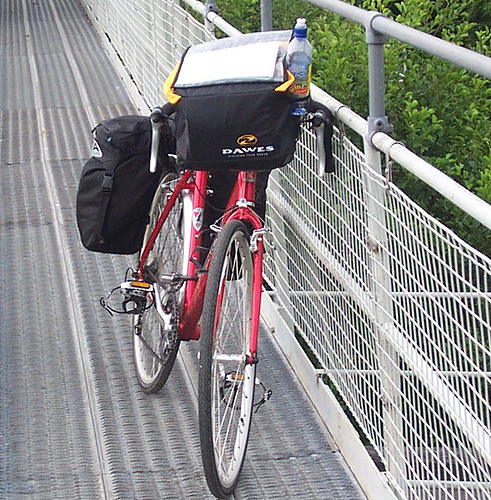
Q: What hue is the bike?
A: Red.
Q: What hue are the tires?
A: Black.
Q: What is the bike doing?
A: Leaning.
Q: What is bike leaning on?
A: The fence.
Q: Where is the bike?
A: On a bridge.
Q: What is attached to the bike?
A: Black bags.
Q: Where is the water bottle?
A: On the bike.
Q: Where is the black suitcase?
A: On the bike.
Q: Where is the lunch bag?
A: On the bike.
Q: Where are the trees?
A: Behind the bridge.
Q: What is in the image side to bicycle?
A: Fence.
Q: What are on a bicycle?
A: Handlebars.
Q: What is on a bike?
A: Black bag.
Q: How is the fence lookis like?
A: Long.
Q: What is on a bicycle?
A: Wheel.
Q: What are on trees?
A: Green leaves.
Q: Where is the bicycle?
A: On bridge.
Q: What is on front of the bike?
A: Black bag.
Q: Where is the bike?
A: On the bridge.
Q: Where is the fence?
A: On the side of the bridge.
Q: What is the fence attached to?
A: Metal poles.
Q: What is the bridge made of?
A: Metal.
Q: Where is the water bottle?
A: On the bike.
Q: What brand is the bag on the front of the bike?
A: Dawes.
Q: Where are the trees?
A: On the other side of the bridge.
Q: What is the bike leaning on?
A: The fence.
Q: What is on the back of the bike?
A: A bag.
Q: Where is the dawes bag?
A: On the front of the bike.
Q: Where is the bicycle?
A: On a metal bridge.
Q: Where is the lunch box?
A: On the bicycle.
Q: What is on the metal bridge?
A: A red bicycle.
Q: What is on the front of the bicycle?
A: A lunch box.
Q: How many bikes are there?
A: One.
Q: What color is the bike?
A: Red.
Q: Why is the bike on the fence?
A: It is parked.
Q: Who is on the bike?
A: Unoccupied.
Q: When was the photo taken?
A: Day time.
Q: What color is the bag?
A: Black.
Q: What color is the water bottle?
A: Blue.